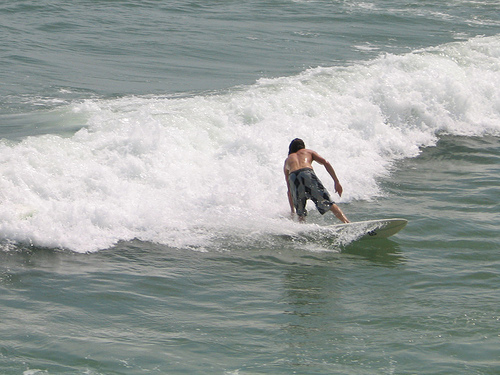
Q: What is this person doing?
A: Surfboarding.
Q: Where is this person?
A: The ocean.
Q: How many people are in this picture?
A: One.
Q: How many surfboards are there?
A: One.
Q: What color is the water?
A: Blue.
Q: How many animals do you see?
A: None.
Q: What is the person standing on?
A: A surfboard.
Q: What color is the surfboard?
A: White.